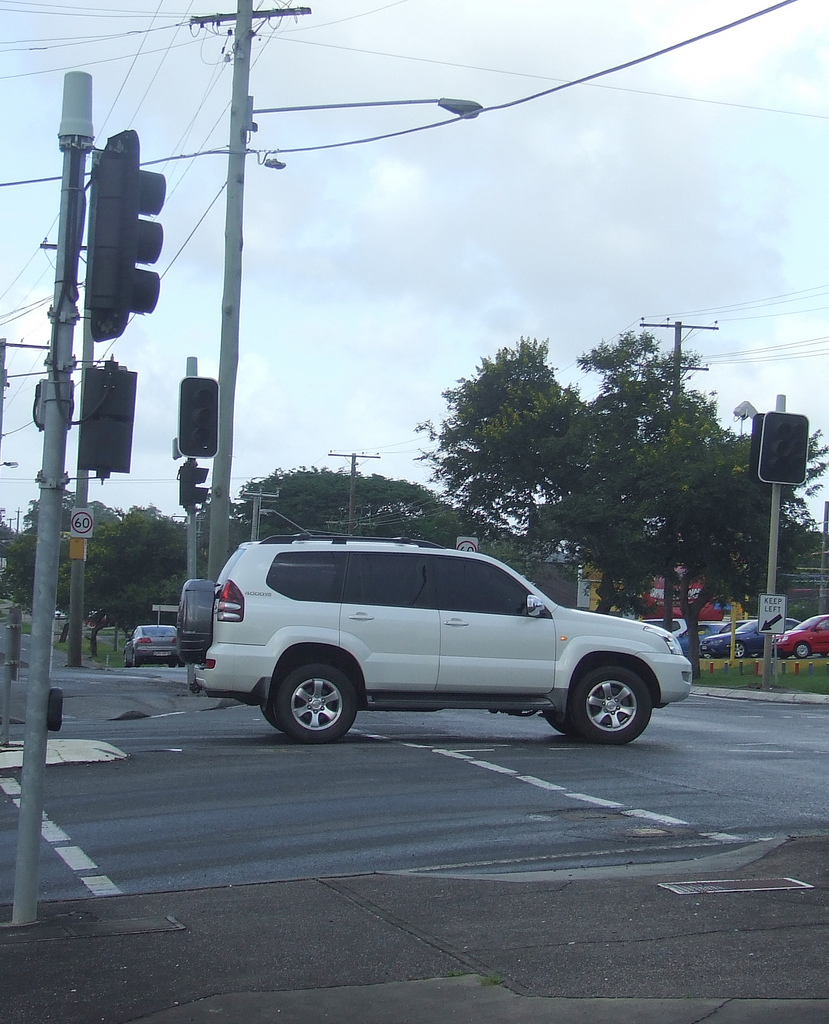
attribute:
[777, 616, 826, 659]
car — red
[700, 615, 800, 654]
car — blue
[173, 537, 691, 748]
car — white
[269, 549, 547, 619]
windows — black tinted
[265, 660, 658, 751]
wheels — black 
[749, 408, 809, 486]
traffic light — off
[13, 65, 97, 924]
pole — gray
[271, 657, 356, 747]
tire — back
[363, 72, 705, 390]
sky — light blue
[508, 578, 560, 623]
view mirror — silver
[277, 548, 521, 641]
window — tinted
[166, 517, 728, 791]
suv — white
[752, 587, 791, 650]
sign — black, white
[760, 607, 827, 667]
car — red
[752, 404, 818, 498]
traffic signal — black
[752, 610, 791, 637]
arrow — black, white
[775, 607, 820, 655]
car — red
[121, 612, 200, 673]
car — small, grey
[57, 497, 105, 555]
traffic sign — white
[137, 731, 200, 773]
paper — white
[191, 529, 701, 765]
car — white 